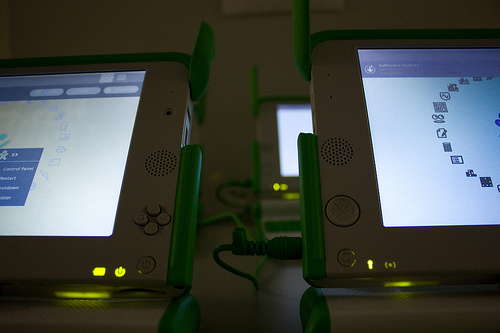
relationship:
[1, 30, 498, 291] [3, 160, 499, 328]
systems on table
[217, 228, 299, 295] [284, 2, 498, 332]
cord on electronic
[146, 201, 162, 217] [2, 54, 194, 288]
control buttons on electronic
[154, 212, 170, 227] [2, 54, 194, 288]
control buttons on electronic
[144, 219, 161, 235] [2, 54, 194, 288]
control buttons on electronic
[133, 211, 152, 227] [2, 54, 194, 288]
control buttons on electronic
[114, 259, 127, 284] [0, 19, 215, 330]
button on electronic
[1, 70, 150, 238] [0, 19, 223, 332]
screen on computer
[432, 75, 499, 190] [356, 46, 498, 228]
images on screen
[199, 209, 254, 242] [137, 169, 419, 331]
wire on table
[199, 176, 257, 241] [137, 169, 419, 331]
wire on table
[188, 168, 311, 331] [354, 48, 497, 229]
table with systems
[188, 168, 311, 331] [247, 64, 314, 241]
table with game system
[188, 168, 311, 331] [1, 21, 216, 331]
table with game system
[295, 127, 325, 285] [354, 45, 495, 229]
side bar of system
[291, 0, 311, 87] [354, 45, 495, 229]
side bar of system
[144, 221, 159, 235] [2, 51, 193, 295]
control buttons on monitor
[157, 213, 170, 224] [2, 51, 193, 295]
control buttons on monitor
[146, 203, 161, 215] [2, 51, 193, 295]
control buttons on monitor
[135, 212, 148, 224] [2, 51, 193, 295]
control buttons on monitor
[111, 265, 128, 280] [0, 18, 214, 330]
power indicator on monitor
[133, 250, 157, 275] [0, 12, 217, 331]
power button on computer monitor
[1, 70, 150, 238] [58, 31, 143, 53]
screen on wall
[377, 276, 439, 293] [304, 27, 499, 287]
glow from screen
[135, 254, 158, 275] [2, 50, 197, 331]
power button on computer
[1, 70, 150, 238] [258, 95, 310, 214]
screen on wall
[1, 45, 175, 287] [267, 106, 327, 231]
screen on wall